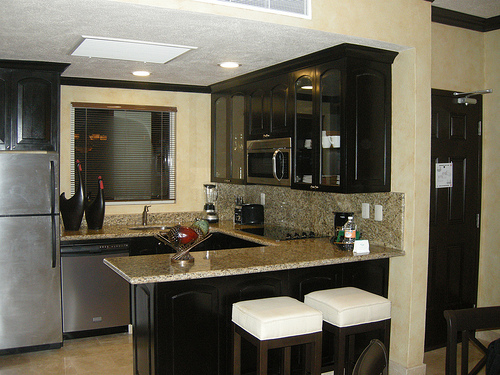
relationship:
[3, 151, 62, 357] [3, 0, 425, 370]
fridge in kitchen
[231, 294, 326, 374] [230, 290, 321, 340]
bar stool with cushion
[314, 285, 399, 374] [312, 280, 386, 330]
bar stool with cushion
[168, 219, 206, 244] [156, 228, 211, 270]
acorns on a stand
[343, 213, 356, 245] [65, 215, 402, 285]
water bottle on counter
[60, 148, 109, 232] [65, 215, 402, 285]
hens on counter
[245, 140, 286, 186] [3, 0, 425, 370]
microwave in kitchen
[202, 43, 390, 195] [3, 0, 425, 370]
cabinets in kitchen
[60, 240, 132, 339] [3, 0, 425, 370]
dishwasher in kitchen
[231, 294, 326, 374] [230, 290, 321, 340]
bar stool with a cushion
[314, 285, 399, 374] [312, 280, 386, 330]
bar stool with a cushion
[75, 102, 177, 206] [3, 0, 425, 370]
window in kitchen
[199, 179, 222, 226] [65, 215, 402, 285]
blender on counter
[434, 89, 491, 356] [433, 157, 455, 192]
door with sign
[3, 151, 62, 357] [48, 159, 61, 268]
fridge with handles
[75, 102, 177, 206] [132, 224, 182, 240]
window above sink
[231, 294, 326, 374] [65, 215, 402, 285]
bar stool at counter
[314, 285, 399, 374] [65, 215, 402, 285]
bar stool at counter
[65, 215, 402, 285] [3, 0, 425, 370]
counter in kitchen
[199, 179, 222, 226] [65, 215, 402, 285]
blender on top of counter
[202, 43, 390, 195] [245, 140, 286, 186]
cabinets and microwave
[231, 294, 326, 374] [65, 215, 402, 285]
bar stool sitting at counter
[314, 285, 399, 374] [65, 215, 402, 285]
bar stool sitting at counter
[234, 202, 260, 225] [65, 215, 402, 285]
toaster on top of counter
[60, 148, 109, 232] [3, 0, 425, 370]
hens in kitchen